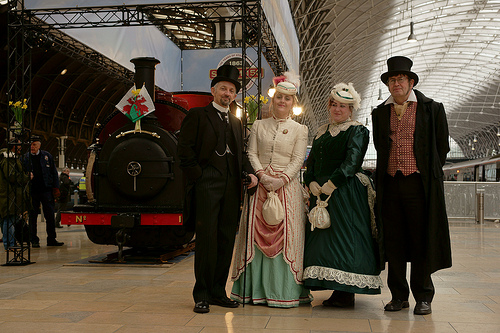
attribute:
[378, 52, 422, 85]
hat — black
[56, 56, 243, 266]
train — black, red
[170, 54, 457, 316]
group — singing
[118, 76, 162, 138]
flag — white, red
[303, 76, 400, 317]
woman — green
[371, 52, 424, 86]
hat — black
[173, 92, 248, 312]
suit — black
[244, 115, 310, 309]
dress — white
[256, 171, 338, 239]
purses — white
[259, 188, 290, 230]
purse — white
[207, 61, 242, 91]
top hat — black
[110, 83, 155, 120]
decoration — Christmas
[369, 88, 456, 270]
coat — wool, black, trench coat, long, dark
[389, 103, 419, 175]
vest — red, white, checkered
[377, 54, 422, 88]
top hat — black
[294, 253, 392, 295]
details — white lace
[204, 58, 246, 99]
hat — black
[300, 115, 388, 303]
dress — dark, green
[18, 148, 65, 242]
suit — blue